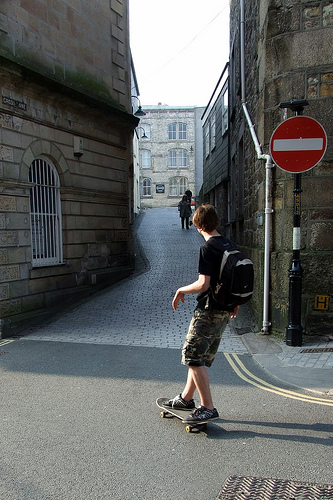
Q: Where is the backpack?
A: On the boy's back.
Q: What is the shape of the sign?
A: Circle.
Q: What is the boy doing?
A: Riding a skateboard.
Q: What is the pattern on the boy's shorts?
A: Camouflage.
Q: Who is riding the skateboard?
A: A boy.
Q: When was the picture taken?
A: Daytime.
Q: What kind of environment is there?
A: Urban.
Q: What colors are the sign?
A: Red and white.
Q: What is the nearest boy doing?
A: Skateboarding.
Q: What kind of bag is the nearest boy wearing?
A: A backpack.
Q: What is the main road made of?
A: Asphalt.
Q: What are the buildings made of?
A: Brick.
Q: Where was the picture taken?
A: In the alley.